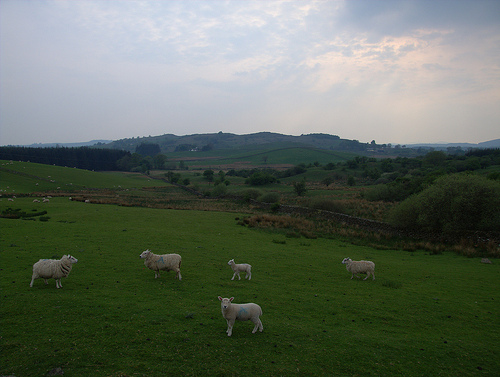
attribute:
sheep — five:
[216, 295, 264, 335]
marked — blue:
[235, 306, 250, 319]